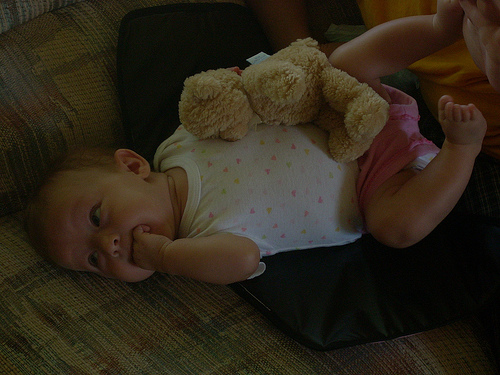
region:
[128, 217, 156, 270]
hand in baby's mouth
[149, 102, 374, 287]
onesie with heart pattern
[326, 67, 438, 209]
baby's pink shorts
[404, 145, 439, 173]
visible portion of diaper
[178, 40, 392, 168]
tan colored teddy bear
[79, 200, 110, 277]
eyes of a baby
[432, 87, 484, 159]
right foot of a baby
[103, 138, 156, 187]
visible ear on a baby's head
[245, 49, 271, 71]
white tag on a teddy bear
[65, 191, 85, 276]
baby's eyebrows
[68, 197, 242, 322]
The baby has her hand in her mouth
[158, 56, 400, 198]
The baby has a bear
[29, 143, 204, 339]
The baby's eyes are open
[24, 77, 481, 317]
The baby is laying down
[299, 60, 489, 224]
The baby has pink shorts on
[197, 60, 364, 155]
The bear is tan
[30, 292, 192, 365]
The couch is light in color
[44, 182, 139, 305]
The baby is looking up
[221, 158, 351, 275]
There are hearts on her shirt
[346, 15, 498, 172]
She has her feet up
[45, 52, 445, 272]
this is a baby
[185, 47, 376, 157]
this is a doll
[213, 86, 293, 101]
the doll is brown in color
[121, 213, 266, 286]
the baby's hand is in ts mouth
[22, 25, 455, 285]
the baby is lying on its back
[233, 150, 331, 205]
the t-shirt is white in color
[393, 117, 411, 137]
the short is pink in color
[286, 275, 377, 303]
the object is made of leather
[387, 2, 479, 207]
the feet are raised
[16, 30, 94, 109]
this is a couch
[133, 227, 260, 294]
a white baby's hand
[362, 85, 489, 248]
a white baby's leg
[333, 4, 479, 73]
a white baby's leg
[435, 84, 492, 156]
a white baby's foot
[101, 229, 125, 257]
a white baby's nose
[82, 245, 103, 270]
a white baby's eye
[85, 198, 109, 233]
a white baby's eye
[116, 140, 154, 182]
a white baby's ear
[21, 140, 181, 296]
a white baby's head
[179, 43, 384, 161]
a white baby's toy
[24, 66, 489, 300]
Baby girl lying on her back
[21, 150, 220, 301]
Baby with fist in her mouth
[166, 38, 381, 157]
Small stuffed teddy bear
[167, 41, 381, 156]
Light brown teddy bear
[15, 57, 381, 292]
Baby holding a teddy bear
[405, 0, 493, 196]
Barefoot baby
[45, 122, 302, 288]
Baby girl wearing white shirt with small pink and yellow hearts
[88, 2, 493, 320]
Baby lying on a black changing pad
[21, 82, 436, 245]
Baby girl with pink shorts on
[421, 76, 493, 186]
Baby curling her toes